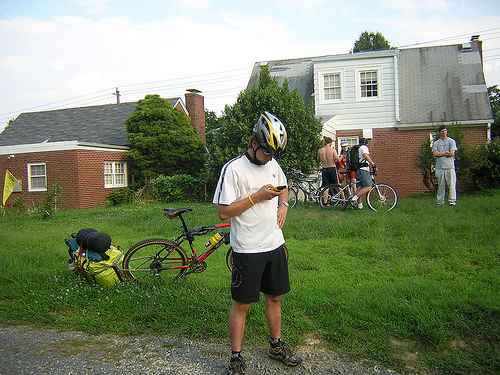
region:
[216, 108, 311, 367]
the man is looking at his cell phone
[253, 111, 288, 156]
the man is wearing a helmet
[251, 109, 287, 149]
the helmet is yellow and grey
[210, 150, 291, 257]
the man is wearing a white shirt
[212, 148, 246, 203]
the shirt has black stripe on it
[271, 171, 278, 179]
the shirt has a brand logo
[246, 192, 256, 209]
the man is wearing a yellow wrist band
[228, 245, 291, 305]
the man is wearing black shorts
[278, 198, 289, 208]
the man is wearing a watch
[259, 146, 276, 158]
the man is wearing sunglasses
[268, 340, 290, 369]
This man is wearing shoes that are off gray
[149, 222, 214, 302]
This man has a bike that is orange and black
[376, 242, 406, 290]
The grass of this apartment complex is green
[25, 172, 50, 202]
The window in the building has a white frame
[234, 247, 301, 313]
This man is wearing a pair of black shorts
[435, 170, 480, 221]
This man is wearing a pair of khaki pants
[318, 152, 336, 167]
This man is going shirtless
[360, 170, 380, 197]
This man's shorts are a deep gray color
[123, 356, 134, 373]
The texture of this area is sharp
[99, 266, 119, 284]
This man has a lime green pack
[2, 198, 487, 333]
large back yard with green grass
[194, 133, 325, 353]
young man with safety bike helmet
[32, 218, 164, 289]
yellow and black backpack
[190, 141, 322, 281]
young man with white t shirt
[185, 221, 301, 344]
young man with black bicycle shorts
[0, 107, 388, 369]
young man standing on gravel road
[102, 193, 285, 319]
old racer bicycle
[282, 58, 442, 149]
two windows in an upstairs bedroom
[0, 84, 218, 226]
small brick house with chimmney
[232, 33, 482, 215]
medium brick house with upstairs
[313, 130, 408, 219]
Men with bicycles standing around in back yard.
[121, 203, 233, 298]
Red bicycle parked on grass of back yard.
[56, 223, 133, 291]
Camping geared packed together.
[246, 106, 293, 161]
Young man wearing black, gray and yellow helmet.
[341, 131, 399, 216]
Man on bicycle wearing black backpack.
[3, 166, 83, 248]
Yellow flag extending from packed camping gear.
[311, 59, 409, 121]
Two windows on second floor of house.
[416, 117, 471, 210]
Man standing in back yard with arms crossed.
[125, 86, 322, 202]
Trees growing between houses in back yard.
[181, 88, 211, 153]
Red brick chimney on side of house.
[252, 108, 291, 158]
The helmet of the bicyclist on the phone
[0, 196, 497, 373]
The grass yard of the houses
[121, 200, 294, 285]
The red bicycle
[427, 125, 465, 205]
The person in the white pants and shirt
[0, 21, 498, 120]
The telephone lines behind the houses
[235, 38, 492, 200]
The taller of the two houses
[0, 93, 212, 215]
The shorter of the houses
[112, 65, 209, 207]
The tree between the houses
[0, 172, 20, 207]
The yellow flag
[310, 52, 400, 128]
The square white portion of the tall house